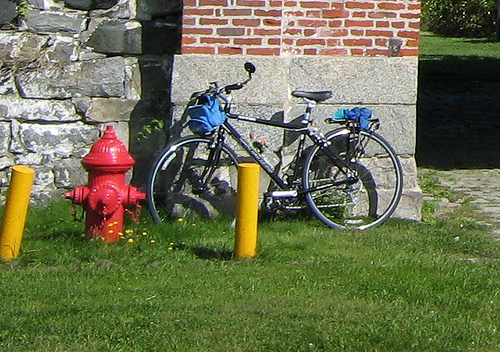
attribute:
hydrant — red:
[66, 125, 154, 245]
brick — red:
[340, 37, 375, 48]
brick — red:
[323, 37, 340, 44]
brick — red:
[294, 37, 325, 47]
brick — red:
[230, 35, 261, 44]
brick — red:
[199, 33, 231, 45]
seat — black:
[290, 88, 331, 100]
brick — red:
[363, 25, 395, 39]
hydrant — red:
[55, 123, 150, 241]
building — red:
[1, 2, 427, 222]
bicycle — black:
[145, 67, 417, 257]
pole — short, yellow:
[235, 162, 257, 256]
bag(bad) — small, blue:
[195, 92, 225, 136]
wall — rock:
[169, 50, 421, 220]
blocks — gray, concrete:
[170, 52, 421, 214]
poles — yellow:
[199, 133, 346, 305]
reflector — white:
[156, 132, 176, 169]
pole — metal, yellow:
[231, 162, 261, 259]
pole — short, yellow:
[0, 162, 37, 264]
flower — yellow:
[128, 222, 178, 257]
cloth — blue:
[332, 105, 372, 131]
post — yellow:
[199, 154, 271, 275]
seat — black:
[275, 79, 350, 111]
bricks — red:
[199, 8, 226, 31]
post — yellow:
[3, 158, 38, 258]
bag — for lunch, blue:
[183, 90, 226, 140]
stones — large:
[0, 0, 135, 194]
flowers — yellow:
[108, 221, 175, 253]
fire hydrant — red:
[65, 125, 145, 244]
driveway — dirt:
[432, 131, 497, 221]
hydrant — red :
[66, 116, 158, 255]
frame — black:
[195, 105, 371, 204]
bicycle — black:
[148, 63, 408, 226]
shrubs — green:
[423, 4, 476, 34]